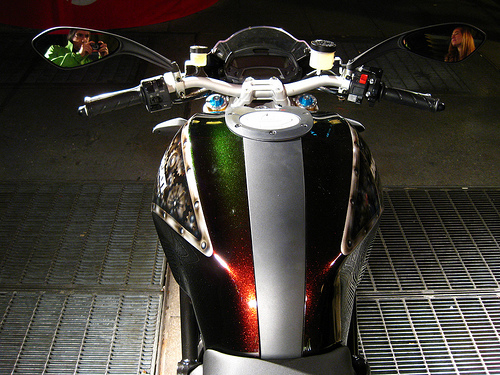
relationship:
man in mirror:
[47, 29, 104, 62] [29, 25, 488, 69]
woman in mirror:
[448, 28, 474, 66] [29, 25, 488, 69]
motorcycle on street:
[25, 20, 492, 373] [0, 1, 499, 373]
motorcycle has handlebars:
[25, 20, 492, 373] [74, 72, 457, 128]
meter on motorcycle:
[224, 52, 299, 83] [25, 20, 492, 373]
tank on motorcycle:
[145, 111, 409, 356] [25, 20, 492, 373]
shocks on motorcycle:
[167, 283, 387, 370] [25, 20, 492, 373]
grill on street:
[2, 172, 500, 372] [0, 1, 499, 373]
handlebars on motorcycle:
[74, 72, 457, 128] [25, 20, 492, 373]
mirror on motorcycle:
[29, 25, 488, 69] [25, 20, 492, 373]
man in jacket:
[47, 29, 104, 62] [47, 44, 92, 67]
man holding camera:
[47, 29, 104, 62] [87, 42, 104, 52]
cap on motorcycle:
[230, 106, 315, 144] [25, 20, 492, 373]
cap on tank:
[230, 106, 315, 144] [145, 111, 409, 356]